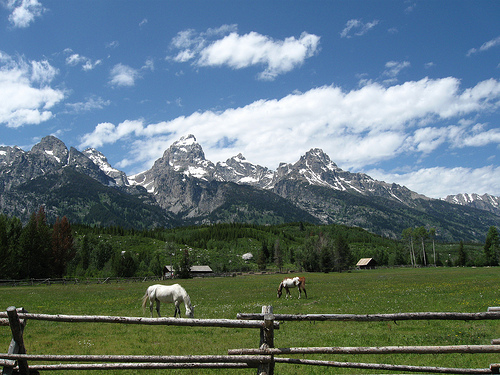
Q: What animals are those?
A: Horses.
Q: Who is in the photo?
A: Nobody.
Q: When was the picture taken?
A: Daytime.